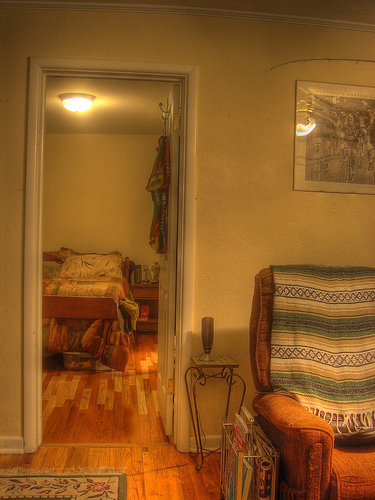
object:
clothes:
[146, 135, 172, 253]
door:
[157, 87, 175, 436]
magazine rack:
[220, 422, 277, 500]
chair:
[250, 264, 374, 499]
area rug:
[1, 471, 127, 499]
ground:
[0, 444, 223, 500]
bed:
[44, 247, 137, 368]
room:
[40, 75, 180, 440]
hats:
[119, 297, 141, 332]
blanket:
[270, 264, 375, 429]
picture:
[293, 80, 375, 194]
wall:
[41, 133, 162, 265]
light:
[60, 95, 93, 113]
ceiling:
[42, 76, 169, 135]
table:
[184, 354, 246, 472]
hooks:
[157, 101, 169, 114]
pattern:
[84, 477, 111, 499]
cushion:
[329, 440, 374, 498]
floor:
[0, 333, 229, 498]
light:
[296, 115, 315, 139]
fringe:
[335, 414, 342, 436]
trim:
[188, 432, 234, 450]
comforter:
[44, 274, 124, 298]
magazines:
[231, 455, 252, 499]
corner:
[109, 469, 126, 487]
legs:
[192, 375, 204, 472]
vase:
[199, 318, 213, 361]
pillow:
[60, 253, 122, 283]